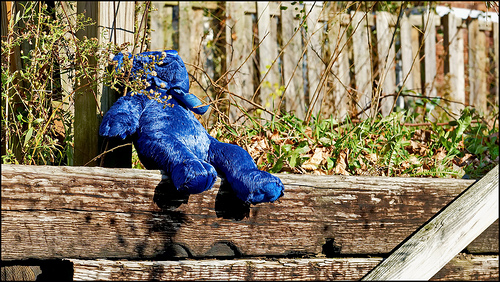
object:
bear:
[98, 49, 285, 206]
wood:
[0, 163, 499, 281]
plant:
[7, 18, 124, 156]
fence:
[228, 10, 470, 113]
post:
[61, 0, 136, 167]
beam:
[350, 15, 372, 121]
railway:
[321, 19, 480, 123]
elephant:
[135, 72, 182, 116]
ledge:
[202, 177, 423, 256]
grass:
[294, 122, 446, 166]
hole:
[350, 39, 355, 121]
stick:
[98, 9, 135, 53]